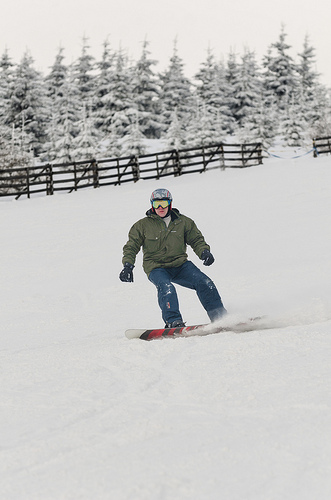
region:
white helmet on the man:
[148, 187, 173, 210]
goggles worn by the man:
[148, 197, 171, 210]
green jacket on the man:
[119, 212, 211, 275]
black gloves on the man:
[117, 247, 215, 284]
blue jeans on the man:
[147, 261, 224, 331]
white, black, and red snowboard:
[124, 318, 227, 344]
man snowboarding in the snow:
[117, 186, 256, 343]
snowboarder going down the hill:
[116, 188, 253, 343]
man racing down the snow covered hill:
[117, 187, 262, 342]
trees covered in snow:
[0, 23, 328, 177]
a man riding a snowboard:
[82, 174, 272, 349]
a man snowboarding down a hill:
[105, 182, 274, 346]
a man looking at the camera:
[102, 186, 248, 337]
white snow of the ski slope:
[91, 383, 224, 472]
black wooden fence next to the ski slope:
[77, 142, 216, 188]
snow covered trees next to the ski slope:
[37, 64, 220, 133]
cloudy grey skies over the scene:
[151, 2, 238, 50]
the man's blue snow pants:
[141, 261, 240, 326]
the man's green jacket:
[126, 211, 209, 270]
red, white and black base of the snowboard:
[132, 324, 203, 342]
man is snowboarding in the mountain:
[102, 186, 286, 339]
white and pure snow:
[20, 378, 291, 493]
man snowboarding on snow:
[116, 185, 293, 344]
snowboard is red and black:
[124, 329, 204, 339]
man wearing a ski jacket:
[125, 216, 201, 263]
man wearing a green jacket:
[129, 218, 193, 264]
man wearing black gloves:
[118, 265, 134, 282]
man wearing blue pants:
[151, 265, 229, 317]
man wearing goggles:
[152, 200, 171, 208]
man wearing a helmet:
[150, 187, 172, 196]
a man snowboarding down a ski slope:
[114, 183, 260, 350]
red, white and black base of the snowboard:
[132, 323, 234, 349]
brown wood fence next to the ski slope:
[64, 144, 187, 189]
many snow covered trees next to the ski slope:
[0, 39, 291, 143]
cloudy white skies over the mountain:
[154, 2, 231, 44]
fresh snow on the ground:
[11, 215, 101, 268]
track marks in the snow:
[264, 303, 305, 340]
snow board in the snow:
[115, 319, 251, 345]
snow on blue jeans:
[160, 277, 183, 317]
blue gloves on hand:
[107, 258, 150, 293]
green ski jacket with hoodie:
[93, 204, 215, 269]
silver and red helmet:
[145, 183, 185, 207]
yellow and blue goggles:
[134, 192, 180, 210]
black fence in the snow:
[108, 139, 249, 177]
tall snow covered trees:
[95, 45, 291, 101]